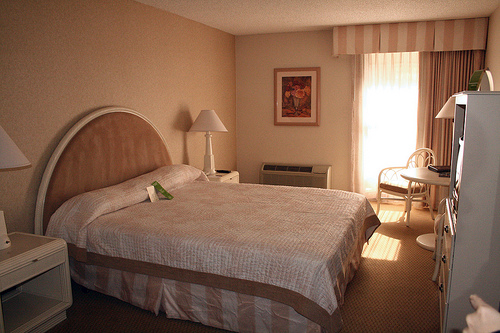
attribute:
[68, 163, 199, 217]
large pillow — white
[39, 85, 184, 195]
headboard — round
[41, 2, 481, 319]
bedroom — clean, tidy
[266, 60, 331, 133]
ruffle — dust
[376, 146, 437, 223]
chair — white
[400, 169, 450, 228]
table — white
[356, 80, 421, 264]
sun — shining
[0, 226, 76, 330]
chest — side